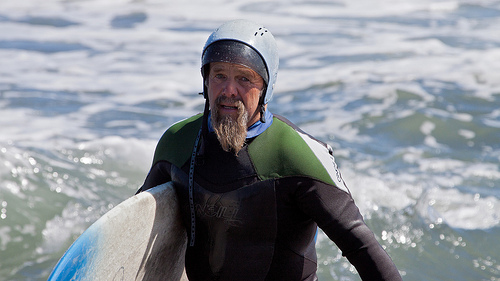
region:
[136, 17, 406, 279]
man wearing wetsuit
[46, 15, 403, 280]
man holding surfboard under his arm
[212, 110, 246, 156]
straggly long grey beard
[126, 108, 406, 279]
green black and white wetsuit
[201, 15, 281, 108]
pale grey and black helmet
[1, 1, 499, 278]
sea is choppy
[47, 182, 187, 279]
blue and white surfboard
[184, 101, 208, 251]
strap hanging down over shoulder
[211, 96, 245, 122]
long grey mustache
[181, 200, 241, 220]
manufacturers logo on front of wetsuit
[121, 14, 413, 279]
Surfer wears a tan helmet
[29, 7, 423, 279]
Surfer holding a surfboard under the arm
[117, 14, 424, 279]
Man wearing surfing apparel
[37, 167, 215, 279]
Surfboard is blue and white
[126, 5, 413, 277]
Man has a grey beard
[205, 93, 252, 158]
Beard is grey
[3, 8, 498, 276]
Background is the sea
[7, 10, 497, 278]
Water is blue and green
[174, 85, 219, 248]
Blue and white helmet strap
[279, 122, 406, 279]
Sleeve is black green and white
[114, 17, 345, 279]
an old man is a carrying a blue and white surfboard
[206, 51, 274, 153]
a man's face has a scraggly gray beard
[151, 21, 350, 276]
a surfer is wearing a green, white and black wet suit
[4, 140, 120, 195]
sunlight is reflected off the ocean's surface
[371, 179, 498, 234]
white waves splash in the background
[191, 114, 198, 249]
a strap dangles from the shoulder of a surfer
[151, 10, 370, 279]
a surfer wears a gray helmet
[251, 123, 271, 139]
a blue collar circles a man's neck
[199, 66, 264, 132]
a man's face sports a gray moustache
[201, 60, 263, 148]
two blue eyes look out from the face of an old man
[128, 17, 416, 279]
Old surfer in the water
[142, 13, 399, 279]
Surfer has grey beard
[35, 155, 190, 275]
Surfboard is white and blue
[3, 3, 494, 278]
Water is choppy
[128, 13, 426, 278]
Surfer has a tan helmet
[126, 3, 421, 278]
Surfer has black and green suit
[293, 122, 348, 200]
White stripe on sleeve of surfer apparel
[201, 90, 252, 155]
beard is grey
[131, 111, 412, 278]
Surfer suit has green in top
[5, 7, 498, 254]
blue and green water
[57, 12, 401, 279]
man in black and green wetsuit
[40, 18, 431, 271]
man holding surfboard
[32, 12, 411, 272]
man wearing silver helmet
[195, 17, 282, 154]
man with long beard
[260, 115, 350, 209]
green and white shoulder patches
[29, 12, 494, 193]
white foam on waves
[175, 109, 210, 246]
blue and black chin strap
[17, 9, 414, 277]
man coming out of the water